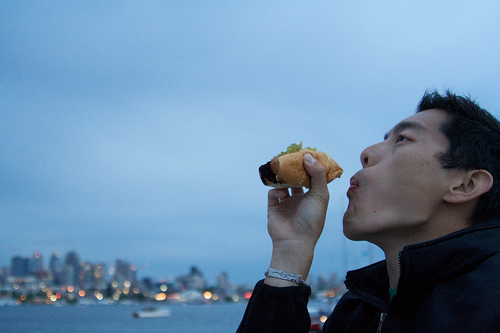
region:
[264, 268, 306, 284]
Bracelet on mans wrist.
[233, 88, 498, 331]
Man in a dark jacket.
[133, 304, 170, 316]
White boat in the water.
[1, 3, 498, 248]
The sky is overcast.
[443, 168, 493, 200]
The ear on the man.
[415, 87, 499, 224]
The man has black hair.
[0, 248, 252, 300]
City light twinkle in the background.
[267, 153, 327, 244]
The hand holding the sandwich.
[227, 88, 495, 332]
Man eating a hot dog in a bun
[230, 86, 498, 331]
Man eating a sandwich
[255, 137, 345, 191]
Hot dog with lettuce in a bun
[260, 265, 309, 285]
Silver bracelet on a man's wrist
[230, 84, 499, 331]
Man wearing a black sweatshirt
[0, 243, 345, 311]
City buildings on a river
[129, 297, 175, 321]
White boat on a river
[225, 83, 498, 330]
Man holding a sandwich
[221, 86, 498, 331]
Man with black short hair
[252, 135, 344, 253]
Hand holding a sandwich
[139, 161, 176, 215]
part of the light blue sky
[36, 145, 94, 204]
part of the light blue sky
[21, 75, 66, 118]
part of the light blue sky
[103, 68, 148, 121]
part of the light blue sky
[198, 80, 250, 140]
part of the light blue sky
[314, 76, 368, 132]
part of the light blue sky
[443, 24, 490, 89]
part of the light blue sky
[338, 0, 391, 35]
part of the light blue sky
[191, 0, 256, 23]
part of the light blue sky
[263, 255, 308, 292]
Man is wearing a bracelet.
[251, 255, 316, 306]
Bracelet is next to the jacket.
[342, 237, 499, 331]
The jacket is black.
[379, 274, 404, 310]
The man is wearing a green shirt.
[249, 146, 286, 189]
The bun is burned.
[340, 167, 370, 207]
The man's mouth is closed.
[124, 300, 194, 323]
The boat is in the water.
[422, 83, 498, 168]
The man's hair is black.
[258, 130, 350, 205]
hot dog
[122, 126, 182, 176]
white clouds in blue sky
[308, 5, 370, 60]
white clouds in blue sky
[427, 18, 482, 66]
white clouds in blue sky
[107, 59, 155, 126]
white clouds in blue sky